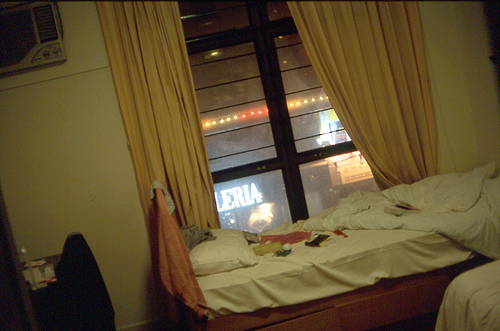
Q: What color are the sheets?
A: White.